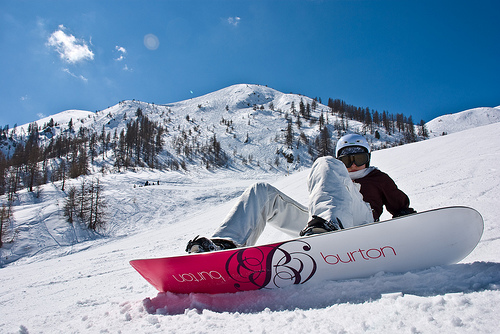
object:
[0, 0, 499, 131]
sky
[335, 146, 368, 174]
face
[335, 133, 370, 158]
helmet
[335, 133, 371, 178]
head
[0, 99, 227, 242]
trees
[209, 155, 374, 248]
pants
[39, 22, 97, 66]
cloud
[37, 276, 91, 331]
snow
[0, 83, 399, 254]
mountain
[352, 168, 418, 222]
jacket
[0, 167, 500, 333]
ground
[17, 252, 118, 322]
snow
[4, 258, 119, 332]
snow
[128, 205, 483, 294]
board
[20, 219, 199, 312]
snow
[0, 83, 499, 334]
snow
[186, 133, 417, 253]
girl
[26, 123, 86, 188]
trees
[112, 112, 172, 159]
trees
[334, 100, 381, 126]
trees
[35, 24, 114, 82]
cloud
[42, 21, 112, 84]
cloud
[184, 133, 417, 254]
man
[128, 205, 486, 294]
snow boarding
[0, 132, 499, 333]
hill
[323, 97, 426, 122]
white chair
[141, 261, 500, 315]
shadow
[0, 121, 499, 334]
snow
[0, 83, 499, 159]
mountain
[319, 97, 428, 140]
trees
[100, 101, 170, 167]
trees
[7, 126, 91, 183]
trees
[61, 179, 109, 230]
trees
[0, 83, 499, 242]
mountain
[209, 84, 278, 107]
top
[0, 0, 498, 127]
distance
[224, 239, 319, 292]
design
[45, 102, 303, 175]
land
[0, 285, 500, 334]
ground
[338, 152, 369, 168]
goggles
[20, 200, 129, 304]
ground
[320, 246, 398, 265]
writing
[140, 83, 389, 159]
mountain